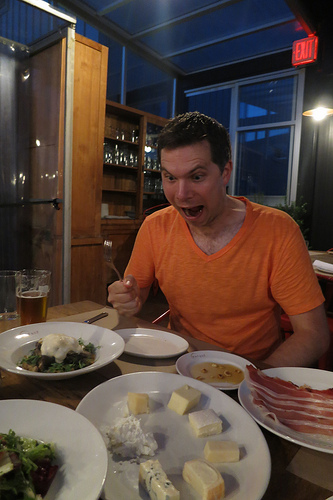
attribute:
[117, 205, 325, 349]
shirt — orange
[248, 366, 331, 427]
bacon — uncooked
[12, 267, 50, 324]
glass — partially filled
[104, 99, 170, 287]
cabinet — wooden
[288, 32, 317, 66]
exit sign — glowing, red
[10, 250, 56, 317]
beer — glass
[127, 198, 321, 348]
shirt — orange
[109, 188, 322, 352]
shirt — orange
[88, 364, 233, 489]
plates — white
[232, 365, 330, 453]
plates — white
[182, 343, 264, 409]
plates — white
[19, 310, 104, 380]
plates — white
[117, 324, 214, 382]
plates — white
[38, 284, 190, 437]
table — brown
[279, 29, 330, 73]
exit sign — red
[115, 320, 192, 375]
plate — empty, white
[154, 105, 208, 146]
hair — brown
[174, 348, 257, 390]
plate — white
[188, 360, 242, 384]
sauce — brown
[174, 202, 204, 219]
mouth — open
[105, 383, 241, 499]
cheese — assorted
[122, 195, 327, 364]
tee shirt — orange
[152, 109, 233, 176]
hair — dark